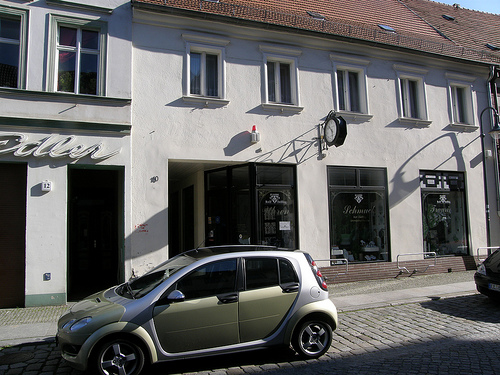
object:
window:
[252, 44, 302, 107]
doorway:
[204, 168, 262, 256]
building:
[0, 0, 499, 308]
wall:
[18, 125, 70, 315]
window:
[327, 162, 390, 264]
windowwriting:
[343, 203, 377, 215]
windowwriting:
[430, 202, 455, 213]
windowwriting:
[261, 200, 296, 219]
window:
[42, 18, 109, 103]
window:
[189, 48, 227, 98]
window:
[337, 66, 367, 116]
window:
[338, 69, 359, 111]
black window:
[338, 67, 360, 111]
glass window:
[335, 70, 360, 111]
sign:
[278, 221, 290, 231]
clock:
[320, 109, 349, 149]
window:
[420, 169, 470, 258]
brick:
[0, 274, 499, 374]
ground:
[370, 292, 410, 303]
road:
[0, 298, 496, 374]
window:
[253, 162, 301, 257]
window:
[398, 74, 429, 120]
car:
[474, 245, 499, 299]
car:
[55, 243, 341, 372]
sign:
[0, 132, 124, 161]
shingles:
[390, 5, 485, 37]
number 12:
[43, 183, 51, 189]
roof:
[132, 0, 498, 66]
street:
[0, 268, 495, 372]